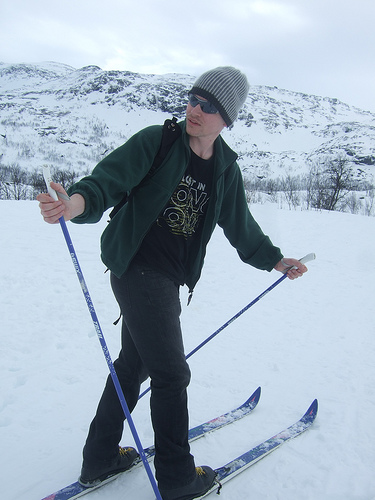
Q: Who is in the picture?
A: A man.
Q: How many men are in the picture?
A: One.